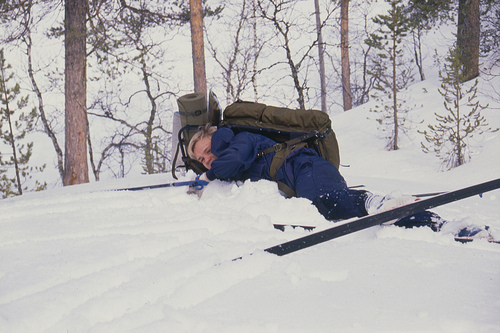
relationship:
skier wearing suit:
[181, 122, 500, 248] [209, 125, 490, 243]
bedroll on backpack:
[177, 92, 208, 174] [222, 100, 339, 167]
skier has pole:
[171, 104, 468, 249] [104, 180, 208, 192]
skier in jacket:
[181, 122, 500, 248] [205, 124, 318, 195]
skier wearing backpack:
[181, 122, 500, 248] [222, 71, 366, 188]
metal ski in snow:
[216, 177, 498, 274] [5, 85, 498, 322]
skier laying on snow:
[181, 122, 500, 248] [19, 225, 167, 322]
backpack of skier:
[217, 100, 338, 194] [187, 91, 494, 242]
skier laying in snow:
[181, 122, 500, 248] [130, 165, 403, 252]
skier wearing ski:
[181, 122, 500, 248] [257, 223, 497, 251]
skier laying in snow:
[181, 122, 500, 248] [175, 160, 496, 263]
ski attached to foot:
[249, 177, 498, 258] [359, 189, 426, 213]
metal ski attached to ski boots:
[272, 177, 498, 272] [364, 192, 418, 224]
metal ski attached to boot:
[272, 177, 498, 272] [444, 209, 491, 249]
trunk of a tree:
[61, 102, 94, 182] [2, 44, 53, 198]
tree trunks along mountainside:
[0, 1, 496, 190] [3, 1, 413, 326]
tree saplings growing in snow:
[354, 7, 488, 178] [41, 200, 217, 327]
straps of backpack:
[268, 145, 289, 162] [171, 87, 348, 178]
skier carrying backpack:
[181, 122, 500, 248] [222, 100, 339, 167]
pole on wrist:
[77, 176, 209, 193] [190, 169, 214, 190]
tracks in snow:
[56, 246, 180, 329] [9, 124, 498, 331]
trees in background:
[4, 1, 481, 198] [1, 2, 457, 131]